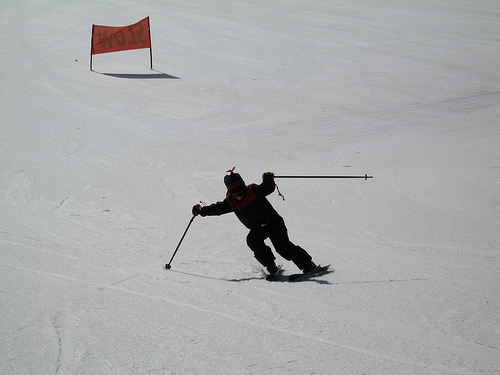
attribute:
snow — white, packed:
[4, 4, 496, 372]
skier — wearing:
[194, 168, 325, 283]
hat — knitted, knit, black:
[224, 167, 247, 195]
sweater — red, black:
[201, 179, 283, 224]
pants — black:
[245, 223, 313, 272]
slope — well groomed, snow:
[2, 2, 490, 166]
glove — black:
[259, 168, 279, 186]